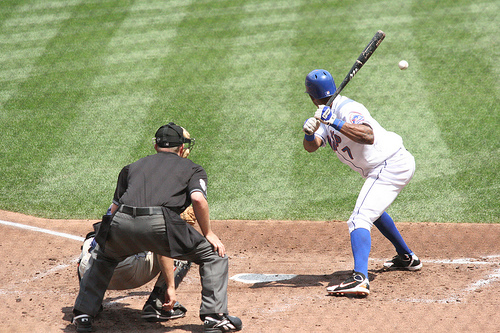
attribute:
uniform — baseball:
[302, 71, 422, 297]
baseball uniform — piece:
[315, 89, 417, 277]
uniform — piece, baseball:
[283, 75, 405, 231]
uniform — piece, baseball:
[349, 143, 420, 234]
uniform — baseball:
[322, 98, 416, 272]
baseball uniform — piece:
[316, 97, 422, 227]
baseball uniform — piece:
[299, 65, 421, 298]